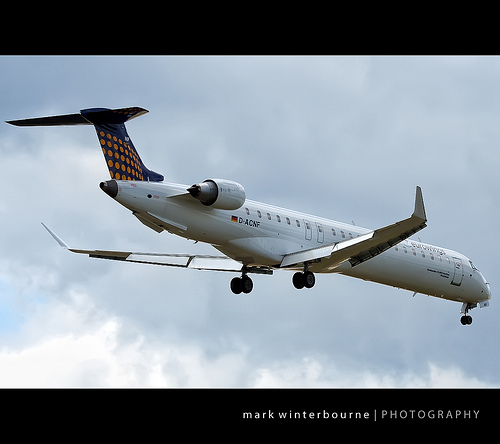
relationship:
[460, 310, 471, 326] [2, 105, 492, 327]
front wheel of airplane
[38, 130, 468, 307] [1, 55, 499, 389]
airplane in sky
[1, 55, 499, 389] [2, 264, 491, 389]
sky has clouds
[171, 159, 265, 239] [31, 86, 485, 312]
engine on plane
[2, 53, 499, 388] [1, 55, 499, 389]
clouds are in sky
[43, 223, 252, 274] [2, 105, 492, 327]
wing on airplane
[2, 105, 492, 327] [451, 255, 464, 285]
airplane has hatch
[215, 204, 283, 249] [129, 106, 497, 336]
emblem on plane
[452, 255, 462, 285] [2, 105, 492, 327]
door in airplane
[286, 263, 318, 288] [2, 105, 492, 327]
wheels of airplane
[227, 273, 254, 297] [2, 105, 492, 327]
wheels of airplane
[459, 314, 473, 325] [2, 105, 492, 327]
front wheel of airplane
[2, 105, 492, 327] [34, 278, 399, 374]
airplane in sky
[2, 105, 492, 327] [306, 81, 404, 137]
airplane in sky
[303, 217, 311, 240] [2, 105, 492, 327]
door of airplane